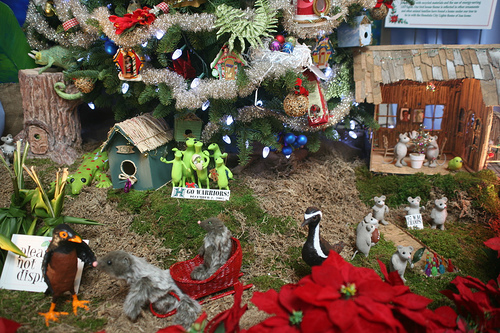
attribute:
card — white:
[1, 233, 88, 296]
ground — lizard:
[396, 156, 422, 197]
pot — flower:
[407, 146, 424, 169]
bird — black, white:
[298, 205, 325, 262]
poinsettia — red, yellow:
[289, 253, 401, 328]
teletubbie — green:
[158, 148, 191, 197]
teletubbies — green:
[106, 46, 150, 88]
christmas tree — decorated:
[26, 2, 413, 164]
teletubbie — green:
[210, 156, 233, 190]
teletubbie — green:
[160, 145, 182, 184]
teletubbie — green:
[190, 138, 211, 185]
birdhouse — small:
[334, 13, 376, 48]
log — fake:
[19, 63, 96, 171]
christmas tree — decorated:
[21, 2, 380, 165]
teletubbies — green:
[401, 188, 448, 226]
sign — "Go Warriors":
[169, 185, 233, 203]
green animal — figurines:
[161, 124, 232, 186]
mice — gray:
[357, 189, 451, 276]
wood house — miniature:
[348, 47, 499, 172]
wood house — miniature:
[95, 111, 178, 195]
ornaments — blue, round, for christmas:
[295, 132, 307, 149]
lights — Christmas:
[153, 28, 255, 152]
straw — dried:
[267, 157, 332, 227]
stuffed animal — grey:
[98, 248, 201, 328]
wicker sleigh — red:
[145, 231, 255, 318]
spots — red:
[78, 151, 108, 180]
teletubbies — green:
[165, 127, 252, 217]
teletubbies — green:
[148, 137, 268, 219]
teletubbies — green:
[158, 136, 249, 206]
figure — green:
[60, 131, 118, 200]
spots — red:
[72, 147, 108, 177]